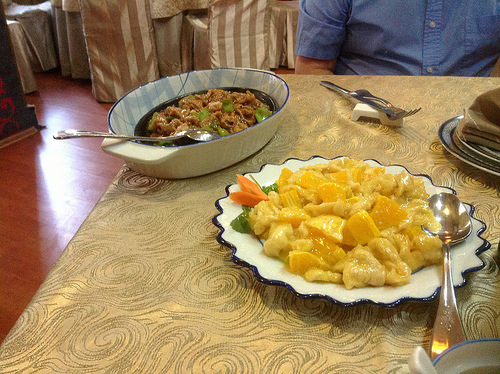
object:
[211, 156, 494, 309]
dish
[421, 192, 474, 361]
spoon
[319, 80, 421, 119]
fork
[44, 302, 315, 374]
table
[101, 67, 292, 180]
bowl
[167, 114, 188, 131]
meat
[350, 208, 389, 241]
potato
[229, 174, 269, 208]
carrot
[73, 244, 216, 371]
cloth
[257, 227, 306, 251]
pasta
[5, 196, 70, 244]
floor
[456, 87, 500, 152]
napkin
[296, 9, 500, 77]
shirt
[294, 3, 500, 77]
person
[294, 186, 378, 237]
cheese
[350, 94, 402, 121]
knife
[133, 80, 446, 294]
food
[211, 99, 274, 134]
bell